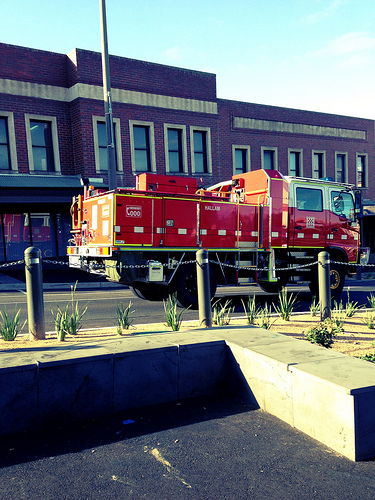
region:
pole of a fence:
[18, 237, 54, 343]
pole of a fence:
[189, 243, 221, 324]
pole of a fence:
[309, 247, 336, 322]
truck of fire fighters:
[52, 148, 362, 313]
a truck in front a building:
[5, 38, 371, 303]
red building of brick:
[4, 40, 373, 182]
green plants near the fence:
[1, 290, 363, 336]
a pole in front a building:
[92, 26, 130, 186]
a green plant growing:
[109, 292, 139, 331]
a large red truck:
[2, 157, 368, 316]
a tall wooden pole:
[96, 1, 117, 201]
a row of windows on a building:
[0, 108, 369, 188]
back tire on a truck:
[163, 265, 220, 318]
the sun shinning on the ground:
[1, 273, 355, 358]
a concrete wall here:
[10, 318, 368, 458]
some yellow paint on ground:
[115, 422, 193, 497]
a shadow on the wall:
[100, 328, 332, 458]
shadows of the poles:
[225, 296, 369, 341]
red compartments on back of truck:
[112, 197, 202, 253]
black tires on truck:
[167, 253, 214, 306]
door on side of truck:
[286, 182, 326, 251]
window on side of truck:
[290, 183, 326, 216]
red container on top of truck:
[138, 165, 201, 191]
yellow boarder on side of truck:
[102, 192, 162, 203]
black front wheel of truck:
[322, 266, 350, 296]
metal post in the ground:
[192, 247, 222, 324]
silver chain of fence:
[58, 252, 187, 276]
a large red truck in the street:
[74, 175, 355, 300]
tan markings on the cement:
[141, 444, 207, 491]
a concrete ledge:
[0, 330, 371, 462]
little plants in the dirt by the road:
[1, 291, 369, 348]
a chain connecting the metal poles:
[0, 253, 374, 270]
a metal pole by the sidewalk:
[22, 246, 48, 338]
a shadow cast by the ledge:
[0, 343, 252, 473]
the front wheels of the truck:
[254, 258, 342, 296]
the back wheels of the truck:
[124, 267, 218, 306]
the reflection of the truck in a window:
[0, 208, 54, 246]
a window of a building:
[23, 110, 60, 175]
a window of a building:
[91, 115, 124, 173]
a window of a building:
[128, 117, 157, 173]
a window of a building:
[163, 121, 187, 175]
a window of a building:
[187, 123, 211, 173]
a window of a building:
[229, 140, 246, 170]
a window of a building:
[285, 146, 300, 177]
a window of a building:
[332, 150, 343, 180]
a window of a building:
[350, 152, 365, 185]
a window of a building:
[306, 146, 328, 183]